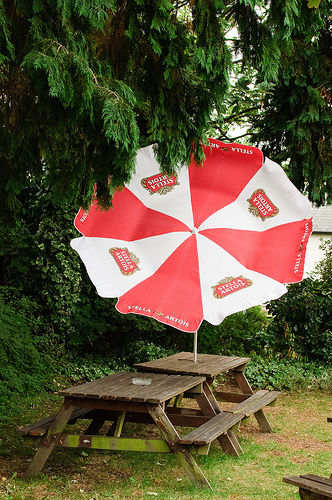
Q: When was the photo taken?
A: Daytime.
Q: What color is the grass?
A: Green.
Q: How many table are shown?
A: Two.